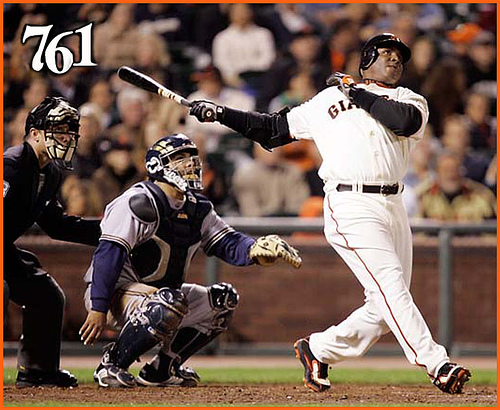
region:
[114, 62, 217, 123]
Black baseball bat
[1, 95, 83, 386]
An umpire wearing black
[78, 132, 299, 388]
A catcher in a squatting position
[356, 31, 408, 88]
Man wearing a black helmet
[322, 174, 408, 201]
Black belt on a man's pants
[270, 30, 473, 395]
Giants baseball player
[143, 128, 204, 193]
Man wearing a catcher's face mask and helmet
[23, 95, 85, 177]
An umpire wearing a helmet and face mask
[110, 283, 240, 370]
Leg guards a catcher is wearing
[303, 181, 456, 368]
White pants with a red stripe down the side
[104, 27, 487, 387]
Baseball player with a bat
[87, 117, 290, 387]
A catcher squatting behind player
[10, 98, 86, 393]
An umpire behind catcher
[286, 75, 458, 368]
White uniform with red print and stripe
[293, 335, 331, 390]
Black, orange and white sports shoe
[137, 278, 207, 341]
Catcher wearing knee pads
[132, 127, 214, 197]
Blue helmet with protective face shield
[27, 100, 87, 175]
Black helmet with protective face shield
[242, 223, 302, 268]
A leather cathers mitt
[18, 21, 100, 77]
The number 761 in white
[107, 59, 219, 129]
The bat is black.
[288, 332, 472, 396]
His shoes are black.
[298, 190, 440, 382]
His pants are white.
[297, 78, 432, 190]
His shirt is white.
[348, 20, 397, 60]
His helmet is black.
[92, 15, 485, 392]
They are playing baseball.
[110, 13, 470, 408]
He is swinging the bat.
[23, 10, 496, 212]
They are watching baseball.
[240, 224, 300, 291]
His mit is tan.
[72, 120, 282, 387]
He is the catcher.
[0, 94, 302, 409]
Man is touching catcher.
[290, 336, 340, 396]
Shoes are orange and white.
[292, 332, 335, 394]
Shoe has black shoe strings.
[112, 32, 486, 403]
Man just hit a baseball.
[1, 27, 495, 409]
Men are wearing helmets.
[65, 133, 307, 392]
Catcher is crouching down by the ground.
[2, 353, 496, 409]
Field has several different terrains.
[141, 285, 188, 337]
Knee pads are blue.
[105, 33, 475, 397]
Man is holding bat.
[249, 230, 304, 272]
Glove is brown and black.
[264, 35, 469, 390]
a baseball player wearing a white uniform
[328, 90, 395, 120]
black lettering on a white baseball shirt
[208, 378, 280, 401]
brown dirt of the baseball diamond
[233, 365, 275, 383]
green grass of the baseball field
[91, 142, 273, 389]
a catcher wearing a grey uniform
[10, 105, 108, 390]
an umpire wearing a black uniform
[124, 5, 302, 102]
many spectators in the stands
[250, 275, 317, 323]
brown brick wall of the stadium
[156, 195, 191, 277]
the catcher's blue pads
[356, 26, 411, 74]
the batter's black baseball helmet